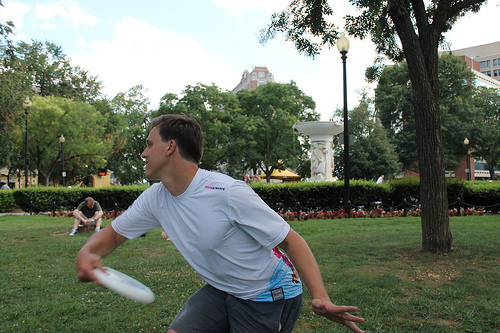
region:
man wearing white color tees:
[200, 195, 265, 285]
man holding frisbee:
[93, 265, 153, 301]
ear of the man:
[162, 138, 174, 156]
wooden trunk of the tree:
[418, 67, 448, 256]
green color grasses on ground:
[23, 255, 68, 318]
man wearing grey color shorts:
[170, 293, 301, 329]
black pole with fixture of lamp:
[57, 131, 67, 181]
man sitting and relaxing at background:
[71, 193, 99, 233]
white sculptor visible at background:
[308, 122, 339, 177]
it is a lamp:
[330, 32, 354, 117]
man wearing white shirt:
[103, 175, 308, 264]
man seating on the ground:
[42, 191, 105, 233]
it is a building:
[442, 46, 498, 147]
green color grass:
[347, 221, 424, 296]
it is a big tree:
[6, 27, 88, 178]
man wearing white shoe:
[58, 223, 103, 235]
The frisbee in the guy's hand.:
[93, 268, 159, 305]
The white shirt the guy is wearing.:
[125, 171, 298, 299]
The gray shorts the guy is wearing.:
[178, 278, 294, 332]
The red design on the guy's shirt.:
[270, 245, 301, 292]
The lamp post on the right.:
[331, 23, 355, 217]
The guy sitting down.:
[69, 198, 107, 233]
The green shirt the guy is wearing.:
[80, 200, 100, 213]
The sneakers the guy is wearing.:
[70, 228, 103, 234]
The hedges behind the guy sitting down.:
[7, 187, 497, 207]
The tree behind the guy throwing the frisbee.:
[277, 0, 497, 262]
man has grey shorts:
[187, 285, 283, 330]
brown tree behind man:
[401, 21, 451, 229]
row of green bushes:
[0, 188, 489, 210]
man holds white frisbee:
[90, 252, 162, 312]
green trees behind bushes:
[5, 62, 482, 179]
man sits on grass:
[70, 188, 113, 241]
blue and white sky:
[102, 3, 233, 83]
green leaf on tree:
[30, 96, 53, 115]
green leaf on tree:
[72, 105, 99, 147]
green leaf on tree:
[120, 114, 132, 124]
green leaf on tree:
[111, 94, 132, 121]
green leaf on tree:
[187, 89, 205, 112]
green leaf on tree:
[216, 87, 236, 115]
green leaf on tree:
[238, 80, 261, 121]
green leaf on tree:
[265, 87, 292, 122]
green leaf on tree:
[268, 127, 295, 152]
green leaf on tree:
[236, 111, 243, 134]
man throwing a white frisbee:
[70, 108, 337, 328]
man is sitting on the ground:
[65, 192, 105, 232]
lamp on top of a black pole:
[332, 30, 353, 196]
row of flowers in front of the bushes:
[320, 207, 407, 221]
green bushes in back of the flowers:
[277, 182, 336, 207]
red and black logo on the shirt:
[202, 178, 229, 195]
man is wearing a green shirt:
[62, 193, 115, 230]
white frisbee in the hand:
[68, 240, 154, 303]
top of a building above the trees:
[237, 61, 277, 87]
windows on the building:
[477, 58, 499, 76]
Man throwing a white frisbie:
[66, 106, 371, 328]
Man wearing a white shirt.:
[82, 107, 304, 310]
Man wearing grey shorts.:
[113, 107, 306, 316]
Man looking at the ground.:
[59, 191, 108, 235]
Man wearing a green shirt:
[65, 192, 105, 235]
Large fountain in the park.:
[276, 105, 356, 199]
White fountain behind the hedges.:
[289, 113, 360, 201]